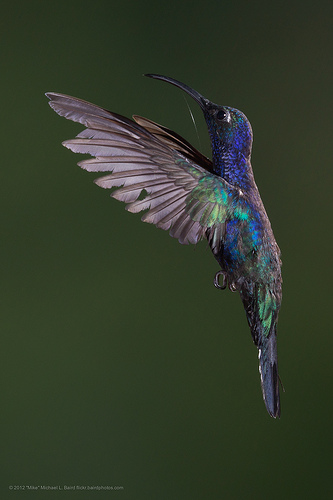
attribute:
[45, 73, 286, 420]
hummingbird — iridescent, green, blue, black, flying, flying upward, teal, purple, in mid air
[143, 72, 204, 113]
beak — long, black, very long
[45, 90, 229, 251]
wing — expanded, extended, spread, feathered, gapped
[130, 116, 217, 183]
wing — expanded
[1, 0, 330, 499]
background — dark, faded green, green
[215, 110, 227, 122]
eye — black, white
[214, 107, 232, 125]
lining — silver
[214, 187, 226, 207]
feather — teal green, royal blue, teal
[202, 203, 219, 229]
feather — light green, black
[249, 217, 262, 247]
feather — purple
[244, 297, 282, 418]
tail — feathered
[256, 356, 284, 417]
tip — black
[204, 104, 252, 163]
head — shades of blue